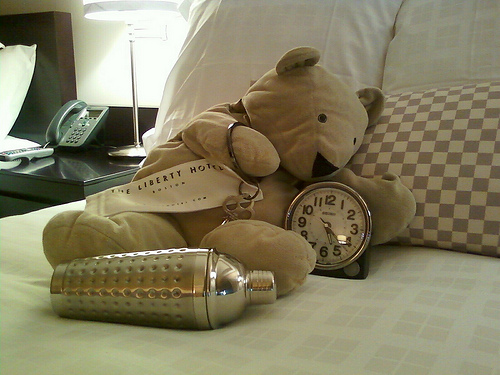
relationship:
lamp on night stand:
[83, 1, 180, 158] [0, 102, 160, 219]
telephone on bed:
[41, 97, 110, 150] [3, 6, 493, 373]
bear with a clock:
[121, 36, 381, 303] [281, 180, 377, 280]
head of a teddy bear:
[239, 47, 390, 184] [53, 57, 388, 292]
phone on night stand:
[37, 95, 109, 152] [3, 127, 140, 212]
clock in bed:
[277, 183, 379, 291] [366, 237, 485, 367]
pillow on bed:
[363, 85, 498, 245] [3, 6, 493, 373]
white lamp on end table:
[81, 2, 181, 157] [1, 136, 141, 206]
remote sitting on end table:
[0, 147, 54, 160] [1, 106, 152, 211]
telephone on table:
[41, 97, 110, 150] [0, 144, 152, 218]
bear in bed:
[121, 36, 381, 303] [2, 200, 497, 374]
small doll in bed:
[40, 45, 417, 298] [2, 200, 497, 374]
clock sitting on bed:
[282, 182, 374, 280] [297, 311, 422, 348]